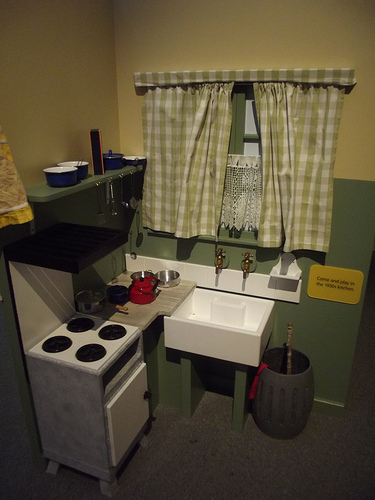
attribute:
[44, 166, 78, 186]
bowl — blue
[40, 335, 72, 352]
burner — black, metal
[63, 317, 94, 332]
burner — black, metal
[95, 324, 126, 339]
burner — black, metal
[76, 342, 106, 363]
burner — black, metal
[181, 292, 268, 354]
sink — toy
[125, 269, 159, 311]
pot — red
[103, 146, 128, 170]
pot — Blue 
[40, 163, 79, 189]
pot — blue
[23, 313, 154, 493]
stove — gray, toy, black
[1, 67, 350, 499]
miniture kitchen — miniature, set up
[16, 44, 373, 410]
kitchen — old-time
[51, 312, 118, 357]
metal burner — black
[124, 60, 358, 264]
curtains — Green, white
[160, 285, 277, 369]
sink — white 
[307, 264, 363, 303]
sign — yellow 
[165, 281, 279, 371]
sink — White 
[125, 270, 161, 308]
teapot — Red 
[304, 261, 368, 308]
sign — yellow